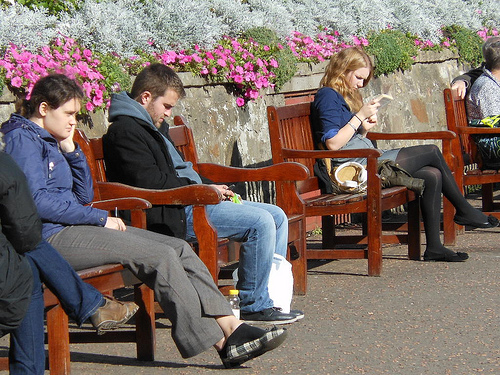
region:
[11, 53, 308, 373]
this is a woman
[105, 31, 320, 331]
this is a man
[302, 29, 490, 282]
woman has legs crossed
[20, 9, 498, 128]
pinks flowers above benches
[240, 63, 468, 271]
the bench is brown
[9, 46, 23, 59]
pink flower on plant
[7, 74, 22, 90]
pink flower on plant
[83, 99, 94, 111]
pink flower on plant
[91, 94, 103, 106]
pink flower on plant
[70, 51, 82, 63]
pink flower on plant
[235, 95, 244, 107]
pink flower on plant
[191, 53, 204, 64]
pink flower on plant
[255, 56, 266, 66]
pink flower on plant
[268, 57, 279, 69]
pink flower on plant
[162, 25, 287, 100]
the flowers are pink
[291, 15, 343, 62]
the flowers are fushia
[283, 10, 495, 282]
the flowers are behind a woman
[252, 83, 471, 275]
the bench is wooden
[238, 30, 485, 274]
a woman is sitting on a bench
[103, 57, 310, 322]
a man is sitting on a bench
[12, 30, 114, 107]
the flowers are pink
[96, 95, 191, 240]
the jacket is black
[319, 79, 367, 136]
the shirt is blue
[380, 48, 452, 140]
the wall is stone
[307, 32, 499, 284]
lady sitting on chair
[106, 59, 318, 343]
lady sitting on chair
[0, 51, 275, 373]
lady sitting on chair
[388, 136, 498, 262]
lady wearing black tights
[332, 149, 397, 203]
white headphones on bench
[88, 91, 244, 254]
man wearing black jacket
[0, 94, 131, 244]
lady wearing blue jacket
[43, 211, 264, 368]
lady wearing grey pants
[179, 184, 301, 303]
man wearing blue jeans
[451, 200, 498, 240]
lady wearing black shoes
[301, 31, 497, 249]
woman wearing a dress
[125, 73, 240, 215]
man wearing black jacket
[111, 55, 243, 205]
man wearing blue jeans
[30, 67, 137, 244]
woman wearing a blue jacket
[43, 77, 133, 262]
woman wearing gray pants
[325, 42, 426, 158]
woman readnig a book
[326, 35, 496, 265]
woman sitting on a bench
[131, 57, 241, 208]
man sitting on a bench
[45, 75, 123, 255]
woman sitting on a bench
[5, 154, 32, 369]
woman wearing black jacket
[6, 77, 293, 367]
girl sitting on bench in blue coat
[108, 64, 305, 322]
man seated on bench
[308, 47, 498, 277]
young girl sitting on bench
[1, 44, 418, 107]
pink flowers on wall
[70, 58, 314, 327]
man in black coat sitting on wooden bench alone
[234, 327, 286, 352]
the womens shoe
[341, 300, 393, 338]
the ground is grey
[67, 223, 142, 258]
women is wearing grey pants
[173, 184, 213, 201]
armrest of the bench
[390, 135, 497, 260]
A pair of black leggings